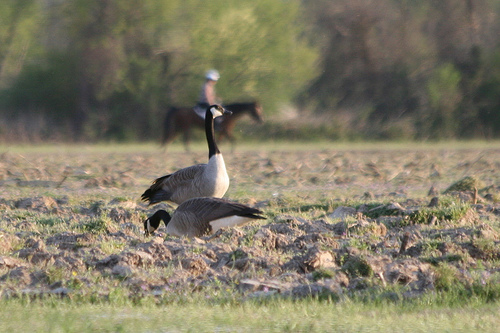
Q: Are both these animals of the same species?
A: No, they are geese and horses.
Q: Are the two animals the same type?
A: No, they are geese and horses.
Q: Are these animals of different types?
A: Yes, they are geese and horses.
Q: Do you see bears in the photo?
A: No, there are no bears.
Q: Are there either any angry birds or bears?
A: No, there are no bears or angry birds.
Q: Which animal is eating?
A: The animal is a goose.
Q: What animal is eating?
A: The animal is a goose.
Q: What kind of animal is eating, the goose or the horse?
A: The goose is eating.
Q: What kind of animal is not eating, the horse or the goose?
A: The horse is not eating.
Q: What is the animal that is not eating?
A: The animal is a horse.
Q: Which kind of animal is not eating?
A: The animal is a horse.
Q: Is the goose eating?
A: Yes, the goose is eating.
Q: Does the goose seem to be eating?
A: Yes, the goose is eating.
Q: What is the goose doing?
A: The goose is eating.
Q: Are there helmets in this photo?
A: Yes, there is a helmet.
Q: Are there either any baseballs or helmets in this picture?
A: Yes, there is a helmet.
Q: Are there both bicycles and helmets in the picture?
A: No, there is a helmet but no bicycles.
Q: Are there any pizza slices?
A: No, there are no pizza slices.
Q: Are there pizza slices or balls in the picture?
A: No, there are no pizza slices or balls.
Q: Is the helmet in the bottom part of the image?
A: No, the helmet is in the top of the image.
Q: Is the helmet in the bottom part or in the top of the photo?
A: The helmet is in the top of the image.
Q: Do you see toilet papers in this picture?
A: No, there are no toilet papers.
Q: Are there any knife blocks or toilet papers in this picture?
A: No, there are no toilet papers or knife blocks.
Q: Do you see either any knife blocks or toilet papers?
A: No, there are no toilet papers or knife blocks.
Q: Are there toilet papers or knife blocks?
A: No, there are no toilet papers or knife blocks.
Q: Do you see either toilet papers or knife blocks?
A: No, there are no toilet papers or knife blocks.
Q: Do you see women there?
A: No, there are no women.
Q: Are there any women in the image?
A: No, there are no women.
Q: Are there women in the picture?
A: No, there are no women.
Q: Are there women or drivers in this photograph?
A: No, there are no women or drivers.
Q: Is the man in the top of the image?
A: Yes, the man is in the top of the image.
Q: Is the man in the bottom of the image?
A: No, the man is in the top of the image.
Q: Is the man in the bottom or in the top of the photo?
A: The man is in the top of the image.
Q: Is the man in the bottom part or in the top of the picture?
A: The man is in the top of the image.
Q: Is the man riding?
A: Yes, the man is riding.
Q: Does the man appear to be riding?
A: Yes, the man is riding.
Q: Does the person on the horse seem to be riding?
A: Yes, the man is riding.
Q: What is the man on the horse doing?
A: The man is riding.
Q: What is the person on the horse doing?
A: The man is riding.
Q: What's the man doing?
A: The man is riding.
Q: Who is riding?
A: The man is riding.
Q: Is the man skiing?
A: No, the man is riding.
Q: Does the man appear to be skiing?
A: No, the man is riding.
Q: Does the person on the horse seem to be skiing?
A: No, the man is riding.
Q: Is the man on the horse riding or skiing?
A: The man is riding.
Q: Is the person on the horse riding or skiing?
A: The man is riding.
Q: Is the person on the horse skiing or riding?
A: The man is riding.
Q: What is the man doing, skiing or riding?
A: The man is riding.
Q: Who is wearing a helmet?
A: The man is wearing a helmet.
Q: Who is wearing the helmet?
A: The man is wearing a helmet.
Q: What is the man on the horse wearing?
A: The man is wearing a helmet.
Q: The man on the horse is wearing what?
A: The man is wearing a helmet.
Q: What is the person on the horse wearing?
A: The man is wearing a helmet.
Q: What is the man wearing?
A: The man is wearing a helmet.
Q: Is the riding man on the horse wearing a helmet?
A: Yes, the man is wearing a helmet.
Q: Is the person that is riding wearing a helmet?
A: Yes, the man is wearing a helmet.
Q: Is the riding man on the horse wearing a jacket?
A: No, the man is wearing a helmet.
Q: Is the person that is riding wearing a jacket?
A: No, the man is wearing a helmet.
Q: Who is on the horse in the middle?
A: The man is on the horse.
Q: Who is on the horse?
A: The man is on the horse.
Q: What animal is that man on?
A: The man is on the horse.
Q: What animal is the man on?
A: The man is on the horse.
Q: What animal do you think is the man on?
A: The man is on the horse.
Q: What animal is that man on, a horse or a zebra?
A: The man is on a horse.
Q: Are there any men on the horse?
A: Yes, there is a man on the horse.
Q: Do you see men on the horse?
A: Yes, there is a man on the horse.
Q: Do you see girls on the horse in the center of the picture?
A: No, there is a man on the horse.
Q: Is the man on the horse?
A: Yes, the man is on the horse.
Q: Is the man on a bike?
A: No, the man is on the horse.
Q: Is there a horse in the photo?
A: Yes, there is a horse.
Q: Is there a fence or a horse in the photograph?
A: Yes, there is a horse.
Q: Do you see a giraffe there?
A: No, there are no giraffes.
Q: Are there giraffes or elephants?
A: No, there are no giraffes or elephants.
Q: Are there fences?
A: No, there are no fences.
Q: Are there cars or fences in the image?
A: No, there are no fences or cars.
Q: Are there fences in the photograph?
A: No, there are no fences.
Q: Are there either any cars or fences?
A: No, there are no fences or cars.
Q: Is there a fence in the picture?
A: No, there are no fences.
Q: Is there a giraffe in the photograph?
A: No, there are no giraffes.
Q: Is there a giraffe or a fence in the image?
A: No, there are no giraffes or fences.